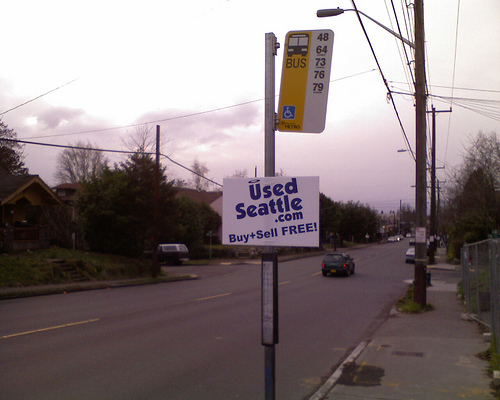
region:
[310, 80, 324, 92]
79 printed in black text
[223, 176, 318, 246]
white advertisement sign with blue lettering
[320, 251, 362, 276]
vehicle on the street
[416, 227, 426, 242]
red and white sign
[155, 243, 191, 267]
parked vehicle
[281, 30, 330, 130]
bus stop sign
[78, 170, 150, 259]
tree with lots of green leaves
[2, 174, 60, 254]
yellow house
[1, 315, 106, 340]
yellow line on the road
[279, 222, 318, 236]
blue text reading FREE!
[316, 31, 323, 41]
a number 4 is written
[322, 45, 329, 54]
a number 4 is written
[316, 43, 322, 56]
a number 6 is written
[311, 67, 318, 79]
a number 7 is written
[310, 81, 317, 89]
a number 7 is written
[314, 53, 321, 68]
a number 7 is written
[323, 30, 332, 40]
a number 8 is written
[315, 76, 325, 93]
a number 9 is written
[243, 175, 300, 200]
a blue word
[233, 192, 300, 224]
a blue word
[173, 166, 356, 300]
white sign with blue letters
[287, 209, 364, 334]
dark car driving down street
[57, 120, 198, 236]
electrical pole in photo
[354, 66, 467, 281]
street lights in photo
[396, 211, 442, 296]
white sign with red letters on pole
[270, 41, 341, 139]
yellow bus stop sign on pole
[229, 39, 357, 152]
handicap placard on yellow bus sign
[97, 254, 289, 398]
street is in photo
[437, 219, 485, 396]
fence in photo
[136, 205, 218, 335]
vehicle parked in driveway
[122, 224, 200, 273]
the car is parked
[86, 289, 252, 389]
the street is gray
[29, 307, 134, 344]
the line is yellow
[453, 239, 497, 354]
the fence is silver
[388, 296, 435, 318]
the grass is green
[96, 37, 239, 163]
the sky is cloudy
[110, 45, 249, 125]
the sky is white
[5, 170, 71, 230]
the roof is brown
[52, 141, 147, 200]
the trees are bare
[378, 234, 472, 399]
the sidewalk is empty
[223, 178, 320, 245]
this is a signboard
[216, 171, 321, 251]
the signboard is rectangular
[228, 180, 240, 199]
the signboard is white in color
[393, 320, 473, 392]
this is a pavement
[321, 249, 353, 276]
this is a car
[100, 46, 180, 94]
this is the sky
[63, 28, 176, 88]
the sky is white in color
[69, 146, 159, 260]
this is a tree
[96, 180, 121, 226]
the leaves are green in color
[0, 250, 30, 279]
the grass is green in color